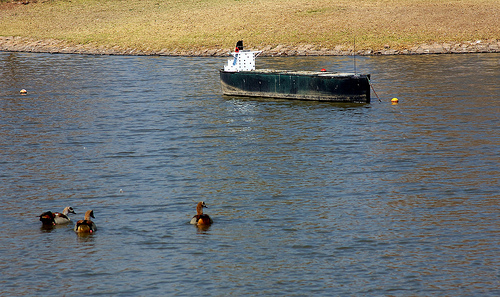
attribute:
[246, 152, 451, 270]
waves — blue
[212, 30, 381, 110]
boat — distant, white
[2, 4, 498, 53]
hill — grassy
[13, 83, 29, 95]
item — floating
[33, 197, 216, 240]
ducks — floating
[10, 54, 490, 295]
water — large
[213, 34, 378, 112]
tanker — toy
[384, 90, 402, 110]
buoy — yellow, orange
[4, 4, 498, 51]
area — dry, grassy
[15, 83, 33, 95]
buoy — yellow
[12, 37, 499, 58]
border — rocky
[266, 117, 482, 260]
water — clear, blue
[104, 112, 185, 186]
water — clear, blue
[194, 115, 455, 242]
water — clear and blue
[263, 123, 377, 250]
water — clear and blue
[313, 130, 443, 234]
water — clear and blue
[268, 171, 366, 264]
water — clear and blue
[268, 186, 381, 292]
water — clear and blue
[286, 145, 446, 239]
water — clear and blue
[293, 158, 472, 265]
water — clear and blue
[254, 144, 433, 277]
water — calm blue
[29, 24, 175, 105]
shore — rocky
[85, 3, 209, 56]
grass — dead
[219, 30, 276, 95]
cover — white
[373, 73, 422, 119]
flatation device — orange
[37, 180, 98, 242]
duck — gray